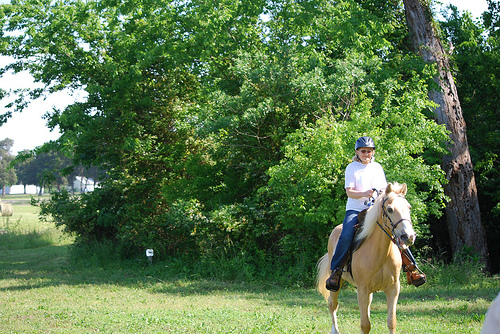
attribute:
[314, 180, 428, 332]
horse — brown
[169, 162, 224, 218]
leaves — green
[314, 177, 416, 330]
horse — tan 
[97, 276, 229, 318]
grass — green 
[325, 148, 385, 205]
man — light skinned